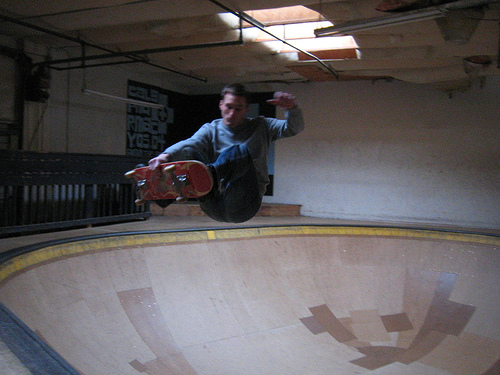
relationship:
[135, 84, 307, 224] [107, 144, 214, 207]
man on skateboard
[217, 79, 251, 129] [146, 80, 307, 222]
head on person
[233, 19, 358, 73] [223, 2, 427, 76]
light from window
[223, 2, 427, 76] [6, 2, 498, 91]
window on ceiling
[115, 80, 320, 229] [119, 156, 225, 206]
man on skateboard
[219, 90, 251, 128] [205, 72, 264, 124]
face on person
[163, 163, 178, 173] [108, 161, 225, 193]
wheel on skateboard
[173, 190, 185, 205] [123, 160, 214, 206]
wheel on red skateboard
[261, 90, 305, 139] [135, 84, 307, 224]
arm on man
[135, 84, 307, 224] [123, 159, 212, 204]
man doing jump on skateboard